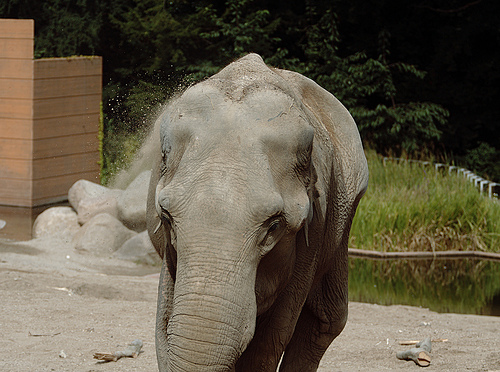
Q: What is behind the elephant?
A: Wall.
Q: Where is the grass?
A: Behind the elephant.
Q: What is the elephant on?
A: Dirt.